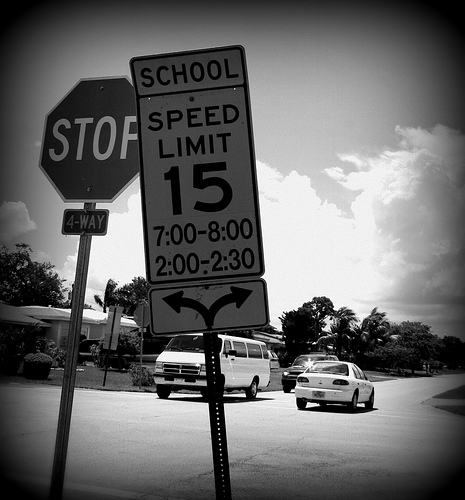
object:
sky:
[0, 2, 460, 114]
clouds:
[259, 114, 461, 341]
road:
[1, 411, 464, 498]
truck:
[281, 353, 339, 393]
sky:
[138, 44, 454, 257]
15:
[164, 161, 234, 216]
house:
[0, 303, 52, 367]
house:
[20, 304, 137, 359]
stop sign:
[39, 76, 146, 203]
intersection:
[0, 379, 460, 497]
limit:
[147, 104, 239, 215]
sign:
[38, 77, 141, 234]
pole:
[103, 307, 118, 387]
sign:
[102, 303, 123, 349]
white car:
[295, 359, 375, 413]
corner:
[0, 352, 73, 500]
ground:
[300, 423, 406, 488]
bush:
[17, 322, 51, 379]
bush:
[127, 360, 152, 386]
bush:
[1, 326, 24, 378]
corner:
[0, 0, 116, 380]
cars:
[151, 331, 271, 403]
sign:
[125, 44, 272, 340]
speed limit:
[146, 103, 239, 216]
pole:
[200, 330, 232, 500]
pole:
[45, 203, 97, 500]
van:
[152, 330, 270, 397]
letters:
[137, 57, 253, 279]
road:
[352, 375, 463, 499]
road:
[0, 350, 463, 497]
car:
[281, 352, 339, 394]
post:
[102, 305, 124, 351]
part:
[260, 21, 450, 151]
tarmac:
[9, 366, 450, 485]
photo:
[0, 0, 465, 500]